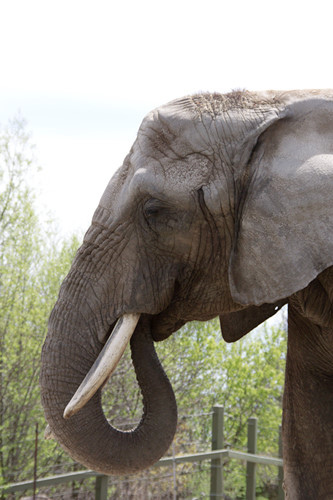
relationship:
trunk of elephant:
[40, 289, 178, 478] [36, 85, 330, 497]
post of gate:
[95, 405, 282, 500] [2, 403, 284, 498]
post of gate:
[274, 422, 283, 499] [2, 403, 284, 498]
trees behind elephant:
[174, 336, 281, 435] [36, 85, 330, 497]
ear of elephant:
[225, 94, 332, 308] [36, 85, 330, 497]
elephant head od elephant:
[103, 87, 305, 344] [36, 85, 330, 497]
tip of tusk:
[59, 409, 72, 420] [61, 314, 137, 421]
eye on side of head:
[144, 198, 166, 217] [72, 88, 330, 335]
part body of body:
[287, 327, 318, 446] [39, 86, 322, 498]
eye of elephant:
[144, 205, 160, 216] [36, 85, 330, 497]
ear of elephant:
[202, 165, 300, 339] [36, 85, 330, 497]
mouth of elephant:
[129, 287, 184, 344] [36, 85, 330, 497]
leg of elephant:
[279, 334, 320, 496] [36, 85, 330, 497]